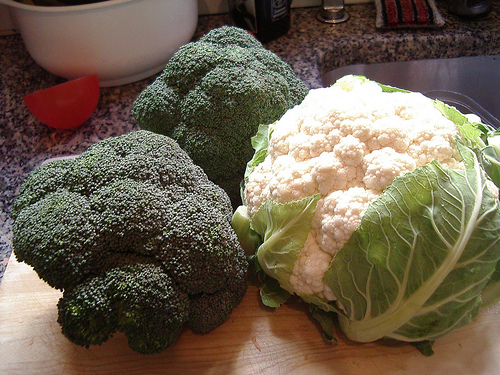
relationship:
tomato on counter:
[23, 75, 97, 130] [2, 3, 498, 268]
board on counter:
[4, 216, 498, 372] [1, 1, 497, 373]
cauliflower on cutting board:
[283, 102, 453, 250] [240, 313, 416, 373]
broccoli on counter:
[129, 26, 311, 205] [1, 1, 497, 373]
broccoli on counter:
[10, 123, 251, 354] [1, 1, 497, 373]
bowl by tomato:
[12, 1, 198, 81] [20, 61, 96, 131]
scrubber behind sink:
[368, 0, 446, 34] [365, 40, 491, 100]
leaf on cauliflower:
[349, 130, 487, 347] [241, 65, 478, 360]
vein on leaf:
[395, 187, 485, 330] [311, 149, 498, 342]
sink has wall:
[331, 44, 498, 131] [437, 51, 494, 111]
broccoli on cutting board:
[10, 110, 260, 354] [18, 291, 488, 343]